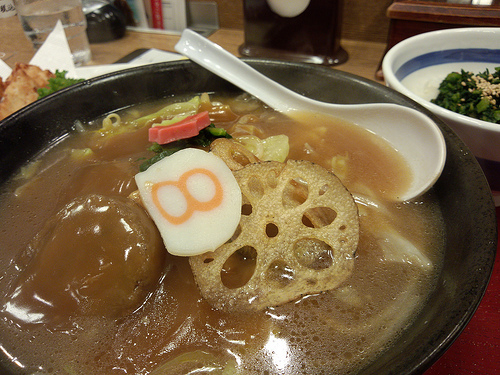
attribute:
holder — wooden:
[232, 1, 361, 73]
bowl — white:
[342, 49, 497, 167]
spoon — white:
[175, 25, 447, 205]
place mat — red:
[464, 169, 494, 366]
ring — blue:
[394, 47, 499, 82]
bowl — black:
[2, 52, 498, 374]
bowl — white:
[384, 27, 499, 147]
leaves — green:
[432, 63, 493, 100]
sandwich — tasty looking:
[2, 62, 82, 121]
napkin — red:
[453, 328, 499, 367]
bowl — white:
[378, 22, 499, 168]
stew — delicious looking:
[2, 89, 447, 371]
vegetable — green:
[425, 65, 484, 121]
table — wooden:
[0, 9, 393, 83]